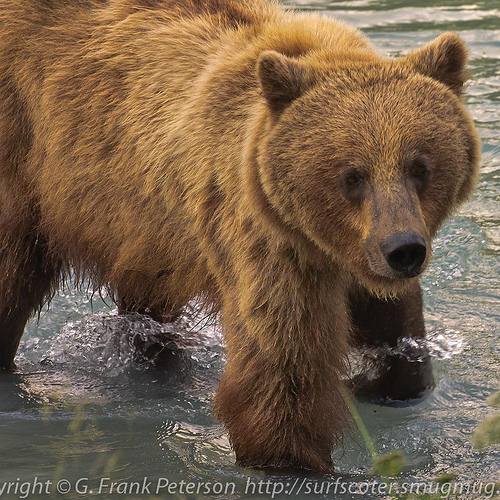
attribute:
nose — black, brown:
[387, 243, 426, 275]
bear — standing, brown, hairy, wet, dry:
[1, 0, 481, 475]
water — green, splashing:
[1, 0, 499, 499]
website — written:
[244, 475, 499, 499]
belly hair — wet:
[49, 236, 215, 319]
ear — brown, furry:
[258, 50, 321, 112]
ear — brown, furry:
[406, 31, 467, 87]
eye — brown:
[343, 172, 362, 186]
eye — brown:
[410, 163, 428, 177]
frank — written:
[99, 478, 152, 496]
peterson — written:
[156, 478, 237, 495]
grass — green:
[37, 389, 126, 474]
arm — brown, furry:
[223, 274, 342, 477]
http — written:
[246, 478, 283, 498]